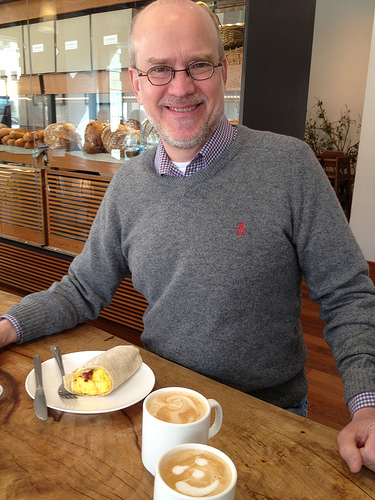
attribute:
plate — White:
[24, 349, 154, 413]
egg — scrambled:
[77, 370, 107, 398]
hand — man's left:
[330, 412, 370, 463]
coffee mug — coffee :
[152, 443, 235, 498]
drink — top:
[160, 447, 231, 496]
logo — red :
[234, 220, 247, 236]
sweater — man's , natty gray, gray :
[0, 124, 374, 406]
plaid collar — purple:
[143, 112, 242, 185]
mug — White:
[152, 441, 237, 497]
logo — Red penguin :
[234, 222, 247, 235]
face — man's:
[130, 3, 223, 147]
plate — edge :
[46, 393, 69, 420]